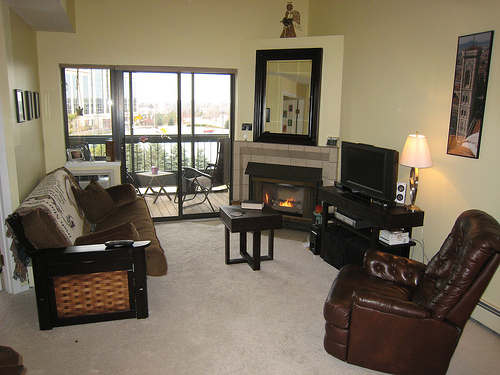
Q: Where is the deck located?
A: Off the living room.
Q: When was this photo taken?
A: In the daytime.